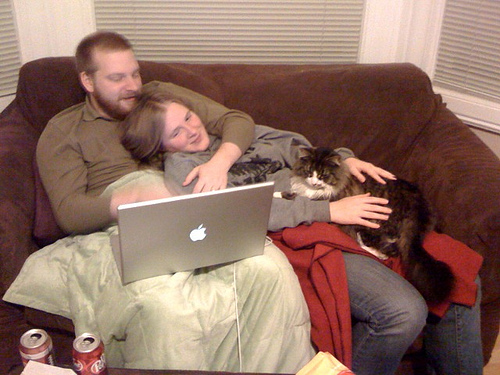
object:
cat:
[270, 141, 453, 308]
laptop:
[106, 178, 274, 287]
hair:
[72, 29, 137, 77]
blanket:
[0, 166, 318, 374]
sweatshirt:
[160, 121, 358, 233]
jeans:
[340, 247, 485, 375]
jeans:
[343, 251, 481, 373]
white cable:
[229, 263, 245, 373]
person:
[118, 94, 488, 374]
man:
[34, 30, 257, 233]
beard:
[90, 89, 143, 121]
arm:
[159, 77, 256, 173]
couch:
[0, 55, 499, 374]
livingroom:
[0, 0, 499, 374]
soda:
[17, 328, 56, 368]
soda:
[66, 330, 107, 373]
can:
[70, 330, 108, 374]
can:
[17, 325, 56, 365]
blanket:
[264, 219, 485, 372]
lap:
[363, 286, 432, 334]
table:
[0, 350, 287, 374]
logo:
[187, 221, 209, 244]